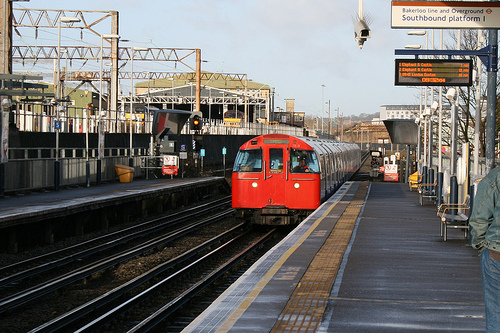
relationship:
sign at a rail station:
[393, 57, 473, 89] [236, 154, 498, 330]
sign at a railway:
[396, 59, 468, 83] [2, 171, 344, 331]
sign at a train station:
[385, 2, 497, 27] [7, 1, 497, 331]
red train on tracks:
[230, 133, 364, 227] [22, 223, 272, 331]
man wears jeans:
[468, 137, 500, 332] [471, 244, 499, 331]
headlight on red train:
[292, 180, 300, 188] [230, 133, 364, 227]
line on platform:
[211, 179, 354, 331] [178, 149, 499, 331]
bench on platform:
[432, 190, 477, 241] [193, 173, 482, 331]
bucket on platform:
[110, 158, 145, 187] [4, 160, 236, 241]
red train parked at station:
[230, 133, 364, 227] [26, 109, 471, 331]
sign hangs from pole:
[391, 0, 500, 30] [482, 27, 499, 178]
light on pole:
[189, 110, 203, 130] [183, 121, 200, 181]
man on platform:
[468, 137, 499, 332] [180, 172, 497, 329]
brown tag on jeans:
[488, 250, 498, 258] [477, 245, 499, 327]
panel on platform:
[384, 115, 431, 142] [230, 188, 477, 328]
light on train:
[245, 168, 304, 192] [199, 111, 384, 222]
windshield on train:
[236, 147, 318, 176] [229, 125, 392, 201]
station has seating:
[0, 0, 497, 330] [435, 180, 472, 243]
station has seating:
[0, 0, 497, 330] [418, 171, 442, 207]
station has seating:
[0, 0, 500, 333] [413, 165, 443, 208]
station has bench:
[0, 0, 500, 333] [436, 193, 471, 241]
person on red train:
[292, 150, 313, 173] [230, 133, 364, 227]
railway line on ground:
[2, 176, 301, 331] [167, 173, 498, 330]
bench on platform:
[436, 193, 471, 241] [179, 165, 474, 328]